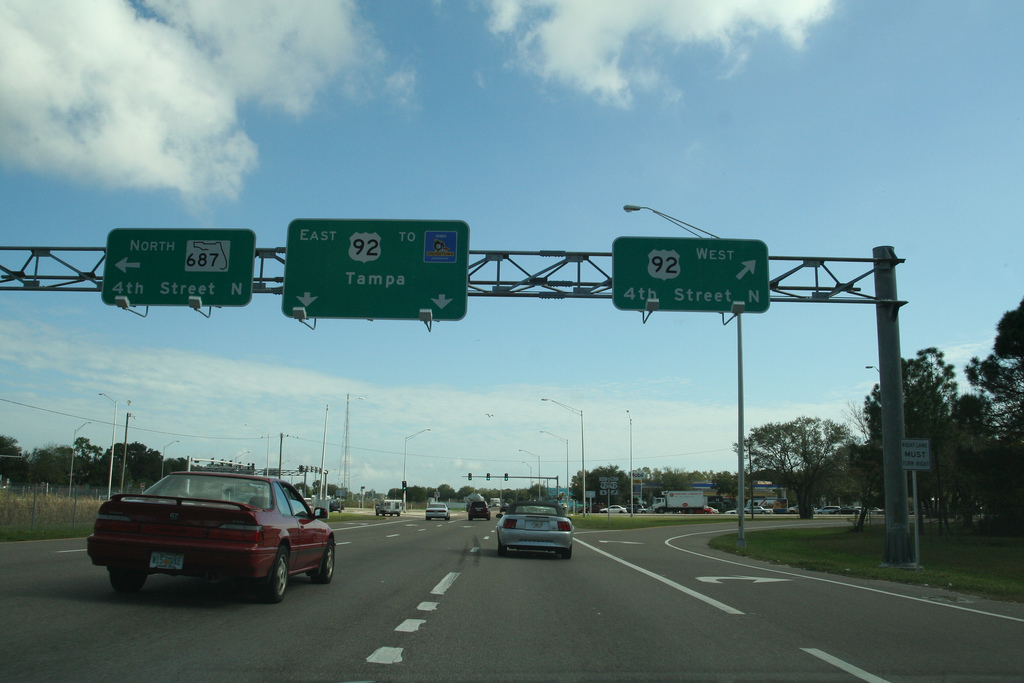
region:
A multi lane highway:
[21, 481, 1017, 679]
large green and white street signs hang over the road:
[85, 215, 793, 332]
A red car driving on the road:
[75, 453, 347, 600]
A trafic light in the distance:
[457, 462, 572, 500]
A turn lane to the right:
[584, 490, 981, 677]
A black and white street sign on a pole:
[894, 427, 936, 571]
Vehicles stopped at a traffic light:
[577, 478, 914, 521]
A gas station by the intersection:
[618, 458, 815, 509]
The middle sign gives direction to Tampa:
[276, 207, 482, 331]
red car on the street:
[85, 463, 335, 593]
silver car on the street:
[484, 493, 574, 564]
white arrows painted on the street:
[598, 520, 783, 597]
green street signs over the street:
[82, 196, 775, 324]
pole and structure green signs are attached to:
[4, 209, 928, 560]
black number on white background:
[644, 244, 680, 279]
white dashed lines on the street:
[334, 497, 509, 666]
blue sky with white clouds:
[7, 13, 994, 453]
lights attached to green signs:
[104, 281, 746, 340]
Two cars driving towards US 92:
[57, 434, 645, 631]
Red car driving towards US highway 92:
[77, 437, 379, 602]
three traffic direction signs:
[42, 140, 827, 384]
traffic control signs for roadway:
[13, 121, 842, 407]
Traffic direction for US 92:
[269, 199, 523, 406]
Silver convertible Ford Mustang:
[473, 465, 609, 586]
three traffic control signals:
[453, 458, 531, 487]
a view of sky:
[373, 92, 671, 225]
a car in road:
[411, 443, 715, 666]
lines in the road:
[335, 601, 440, 674]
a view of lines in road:
[356, 587, 521, 680]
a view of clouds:
[296, 380, 650, 513]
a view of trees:
[799, 402, 1014, 507]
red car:
[84, 463, 354, 610]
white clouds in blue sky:
[258, 21, 439, 108]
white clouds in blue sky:
[553, 11, 652, 73]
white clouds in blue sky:
[526, 111, 664, 201]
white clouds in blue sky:
[823, 112, 957, 179]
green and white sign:
[84, 213, 268, 308]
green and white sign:
[279, 182, 489, 334]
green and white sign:
[597, 208, 784, 332]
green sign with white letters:
[101, 223, 260, 310]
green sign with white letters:
[278, 214, 474, 323]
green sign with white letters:
[607, 230, 772, 319]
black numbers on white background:
[180, 245, 222, 272]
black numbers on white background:
[350, 233, 376, 259]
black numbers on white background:
[650, 246, 680, 273]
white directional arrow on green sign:
[108, 254, 148, 274]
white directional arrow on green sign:
[297, 287, 318, 308]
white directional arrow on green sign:
[731, 254, 757, 280]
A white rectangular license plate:
[133, 533, 198, 588]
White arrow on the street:
[680, 548, 801, 597]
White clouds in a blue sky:
[0, 1, 1018, 489]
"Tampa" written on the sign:
[326, 250, 416, 301]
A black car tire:
[242, 522, 297, 606]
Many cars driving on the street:
[2, 441, 1015, 670]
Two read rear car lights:
[484, 501, 580, 540]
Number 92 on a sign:
[336, 210, 395, 272]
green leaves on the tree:
[997, 452, 1017, 495]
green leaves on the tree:
[918, 355, 953, 413]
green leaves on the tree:
[778, 373, 865, 536]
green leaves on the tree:
[740, 426, 818, 484]